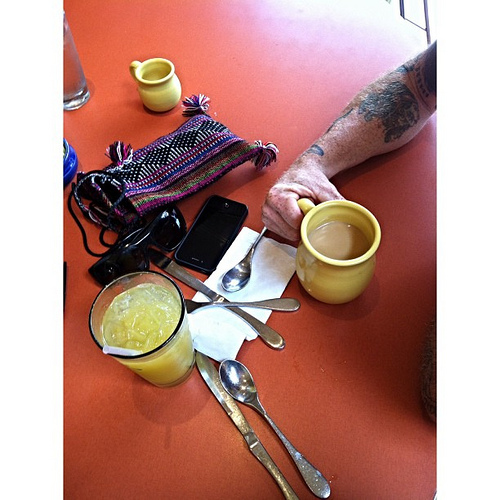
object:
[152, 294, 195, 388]
glass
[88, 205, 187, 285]
sunglasses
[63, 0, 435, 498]
table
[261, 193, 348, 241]
fingers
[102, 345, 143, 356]
straw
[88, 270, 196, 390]
cup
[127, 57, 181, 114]
cup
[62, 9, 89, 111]
cup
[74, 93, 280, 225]
bag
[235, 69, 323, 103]
top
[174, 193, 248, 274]
phone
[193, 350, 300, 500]
knife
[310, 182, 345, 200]
thumb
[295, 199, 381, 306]
cup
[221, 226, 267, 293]
spoon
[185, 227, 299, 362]
napkin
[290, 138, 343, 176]
wrist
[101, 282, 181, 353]
ice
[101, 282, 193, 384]
drink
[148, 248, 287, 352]
knife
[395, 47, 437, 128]
elbow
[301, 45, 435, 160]
tatto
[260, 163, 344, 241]
hand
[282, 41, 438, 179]
arm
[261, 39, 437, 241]
man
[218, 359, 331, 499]
spoon